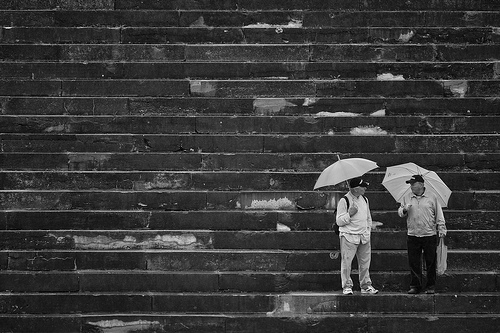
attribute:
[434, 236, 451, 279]
bag — plastic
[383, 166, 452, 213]
umbrella — white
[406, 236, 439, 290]
pants — black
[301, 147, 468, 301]
people — old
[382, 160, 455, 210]
umbrella — lightly colored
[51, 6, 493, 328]
steps — long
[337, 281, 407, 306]
tennis shoes — white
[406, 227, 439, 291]
pants — black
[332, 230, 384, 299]
jeans — blue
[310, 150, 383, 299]
man — holding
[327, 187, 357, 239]
backpack — black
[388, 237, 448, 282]
pants — black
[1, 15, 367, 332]
staircase — long  , concrete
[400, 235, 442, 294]
pants — black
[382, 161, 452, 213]
umbrella — white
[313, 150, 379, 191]
umbrella — white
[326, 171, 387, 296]
person — old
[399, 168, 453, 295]
person — old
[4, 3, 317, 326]
staircase — large, dark, stone